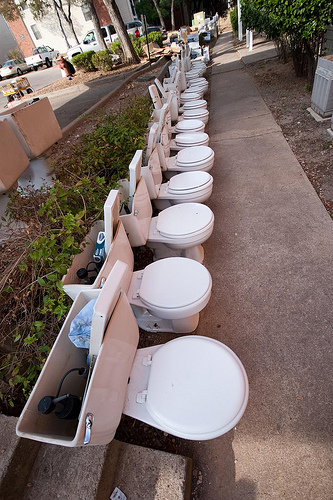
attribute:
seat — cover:
[96, 236, 225, 348]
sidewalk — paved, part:
[210, 16, 284, 187]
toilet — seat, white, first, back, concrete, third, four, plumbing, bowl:
[136, 143, 237, 227]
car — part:
[74, 28, 125, 69]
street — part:
[41, 63, 75, 113]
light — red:
[46, 20, 98, 99]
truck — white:
[75, 10, 144, 84]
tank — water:
[14, 240, 150, 477]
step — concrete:
[218, 60, 255, 119]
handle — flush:
[83, 407, 109, 446]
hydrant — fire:
[52, 27, 89, 89]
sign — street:
[171, 10, 216, 50]